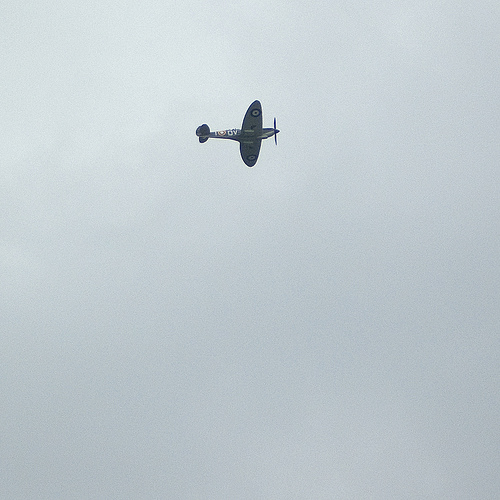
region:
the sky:
[162, 357, 278, 472]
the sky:
[273, 270, 345, 467]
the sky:
[336, 419, 355, 461]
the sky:
[285, 385, 326, 483]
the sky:
[296, 330, 350, 475]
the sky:
[202, 336, 298, 475]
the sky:
[256, 370, 329, 485]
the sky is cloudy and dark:
[166, 397, 176, 419]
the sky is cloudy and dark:
[300, 417, 318, 454]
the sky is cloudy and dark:
[292, 459, 314, 479]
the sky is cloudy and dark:
[285, 460, 303, 481]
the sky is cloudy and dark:
[299, 461, 319, 486]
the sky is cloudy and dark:
[284, 470, 299, 497]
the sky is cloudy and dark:
[302, 463, 330, 496]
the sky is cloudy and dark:
[287, 446, 304, 474]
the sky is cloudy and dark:
[304, 449, 318, 474]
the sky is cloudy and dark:
[317, 452, 331, 481]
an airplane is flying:
[167, 70, 378, 237]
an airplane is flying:
[155, 17, 325, 181]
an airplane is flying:
[200, 85, 307, 222]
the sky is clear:
[304, 433, 329, 467]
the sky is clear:
[316, 451, 326, 469]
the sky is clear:
[302, 455, 313, 479]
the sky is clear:
[262, 448, 279, 461]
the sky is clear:
[283, 473, 292, 498]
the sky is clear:
[294, 443, 303, 463]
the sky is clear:
[306, 451, 311, 452]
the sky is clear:
[269, 440, 281, 452]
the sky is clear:
[291, 440, 306, 455]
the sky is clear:
[282, 445, 297, 451]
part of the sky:
[351, 159, 403, 223]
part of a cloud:
[241, 376, 293, 432]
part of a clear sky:
[316, 257, 376, 312]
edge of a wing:
[248, 165, 260, 177]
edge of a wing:
[238, 155, 253, 170]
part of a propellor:
[273, 130, 282, 158]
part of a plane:
[249, 135, 274, 146]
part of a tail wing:
[193, 80, 215, 160]